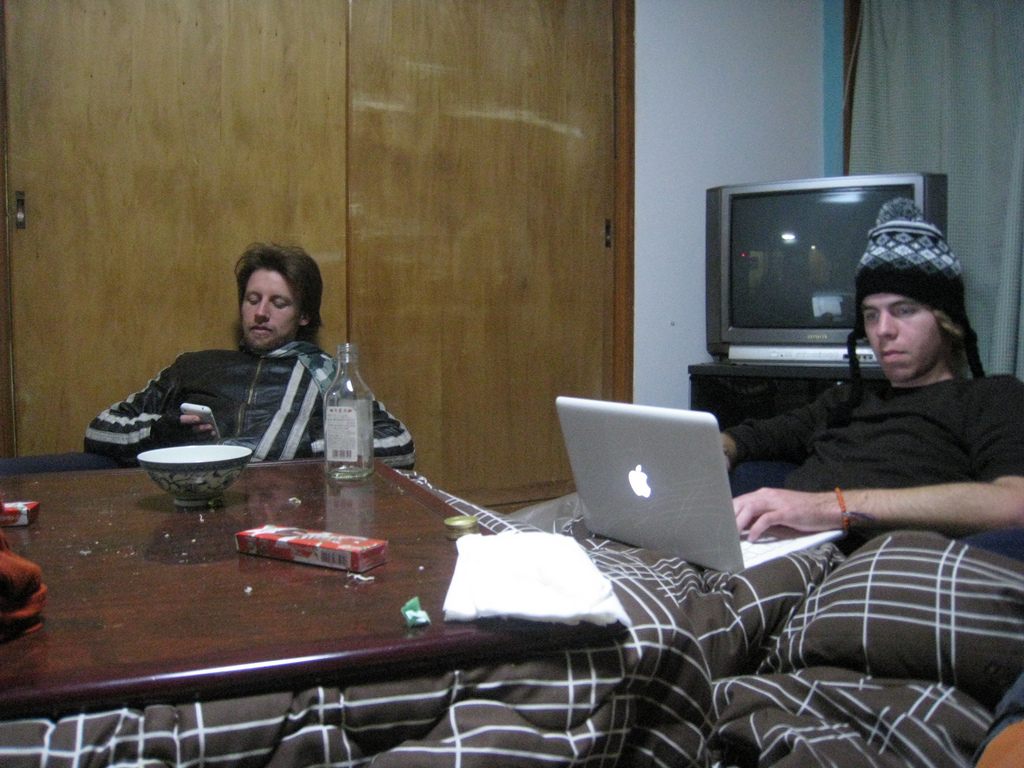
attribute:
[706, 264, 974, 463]
person — sitting, inside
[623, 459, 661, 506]
apple — white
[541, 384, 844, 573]
computer — silver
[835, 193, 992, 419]
ski hat — black, white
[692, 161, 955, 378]
tv — silver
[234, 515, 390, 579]
cigarette box — red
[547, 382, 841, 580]
laptop — silver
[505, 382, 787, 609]
laptop — silver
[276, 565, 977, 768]
blanket — brown and white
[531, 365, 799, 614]
laptop — silver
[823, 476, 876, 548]
bracelet — orange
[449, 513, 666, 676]
napkin — white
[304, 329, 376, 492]
bottle — empty, clear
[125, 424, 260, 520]
bowl — white, blue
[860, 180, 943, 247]
pom pom — grey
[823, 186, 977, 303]
bonnet — black, gray, white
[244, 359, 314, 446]
stripes — white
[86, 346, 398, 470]
jacket — black